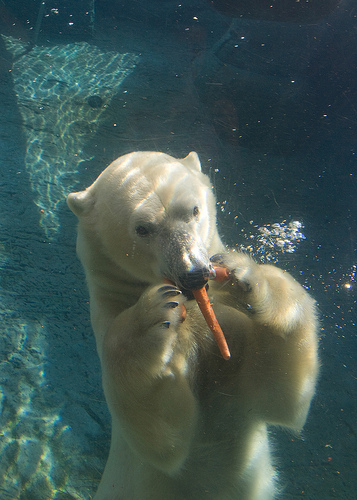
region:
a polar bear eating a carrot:
[62, 147, 333, 474]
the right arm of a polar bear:
[55, 282, 194, 457]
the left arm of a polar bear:
[214, 260, 313, 423]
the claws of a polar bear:
[147, 283, 184, 336]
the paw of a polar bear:
[116, 286, 192, 378]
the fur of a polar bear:
[255, 445, 287, 483]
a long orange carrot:
[191, 289, 236, 370]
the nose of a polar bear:
[172, 257, 211, 296]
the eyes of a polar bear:
[129, 206, 212, 236]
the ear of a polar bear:
[55, 187, 98, 221]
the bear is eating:
[65, 154, 314, 414]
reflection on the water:
[10, 418, 71, 486]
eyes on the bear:
[145, 190, 214, 239]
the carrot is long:
[190, 283, 243, 361]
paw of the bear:
[130, 274, 192, 354]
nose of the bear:
[183, 255, 210, 289]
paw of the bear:
[225, 253, 294, 333]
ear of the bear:
[35, 177, 107, 225]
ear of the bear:
[170, 152, 217, 181]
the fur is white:
[195, 406, 244, 471]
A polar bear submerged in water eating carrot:
[55, 146, 344, 481]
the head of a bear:
[78, 136, 252, 322]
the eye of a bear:
[123, 202, 166, 263]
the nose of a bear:
[164, 246, 235, 304]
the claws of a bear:
[120, 279, 181, 369]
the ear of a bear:
[68, 150, 128, 245]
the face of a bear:
[97, 150, 274, 347]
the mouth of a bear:
[162, 237, 253, 299]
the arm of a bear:
[112, 299, 255, 491]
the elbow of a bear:
[120, 396, 219, 484]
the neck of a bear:
[71, 227, 131, 345]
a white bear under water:
[66, 149, 319, 498]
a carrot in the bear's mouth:
[191, 289, 233, 359]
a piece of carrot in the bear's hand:
[211, 265, 230, 280]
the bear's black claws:
[156, 283, 183, 329]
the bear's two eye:
[134, 204, 200, 238]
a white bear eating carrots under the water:
[6, 4, 351, 496]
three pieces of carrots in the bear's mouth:
[161, 263, 232, 362]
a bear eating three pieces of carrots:
[49, 146, 332, 499]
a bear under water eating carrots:
[17, 145, 345, 497]